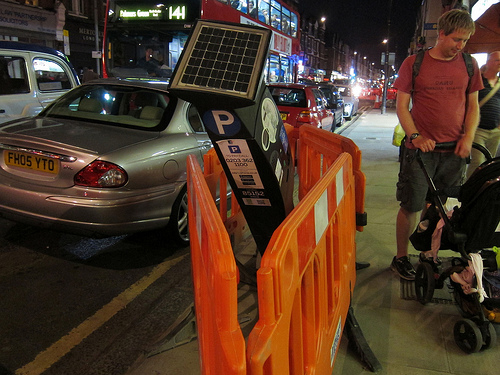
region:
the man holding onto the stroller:
[388, 11, 483, 283]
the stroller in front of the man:
[412, 132, 498, 352]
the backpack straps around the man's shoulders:
[409, 50, 474, 93]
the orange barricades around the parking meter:
[186, 122, 381, 374]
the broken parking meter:
[166, 19, 298, 259]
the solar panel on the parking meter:
[175, 23, 262, 96]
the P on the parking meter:
[209, 109, 234, 134]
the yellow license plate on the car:
[3, 152, 60, 173]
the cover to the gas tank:
[161, 159, 179, 181]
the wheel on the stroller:
[413, 261, 434, 304]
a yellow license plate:
[5, 144, 60, 177]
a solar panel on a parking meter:
[182, 24, 264, 96]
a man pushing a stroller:
[388, 4, 498, 353]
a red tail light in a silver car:
[75, 156, 132, 195]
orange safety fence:
[178, 123, 374, 370]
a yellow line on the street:
[7, 246, 202, 373]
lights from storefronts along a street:
[109, 4, 395, 98]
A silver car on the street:
[0, 73, 259, 253]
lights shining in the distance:
[340, 80, 375, 103]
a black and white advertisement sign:
[116, 5, 193, 22]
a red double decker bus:
[100, 0, 300, 83]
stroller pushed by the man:
[410, 140, 495, 355]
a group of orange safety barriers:
[185, 121, 365, 371]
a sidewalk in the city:
[122, 105, 497, 370]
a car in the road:
[0, 76, 231, 246]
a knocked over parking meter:
[166, 18, 294, 255]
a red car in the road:
[266, 82, 336, 132]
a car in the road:
[0, 40, 90, 123]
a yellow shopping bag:
[391, 121, 405, 146]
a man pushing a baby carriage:
[393, 8, 498, 353]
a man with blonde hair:
[433, 7, 473, 67]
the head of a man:
[435, 8, 475, 62]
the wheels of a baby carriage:
[453, 310, 495, 353]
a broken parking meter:
[176, 15, 306, 238]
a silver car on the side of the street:
[3, 59, 218, 251]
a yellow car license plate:
[1, 145, 60, 177]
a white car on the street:
[0, 28, 78, 123]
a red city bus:
[99, 0, 307, 103]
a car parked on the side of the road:
[262, 78, 335, 142]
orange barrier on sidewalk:
[194, 193, 256, 338]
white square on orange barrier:
[304, 191, 338, 238]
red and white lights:
[62, 154, 135, 200]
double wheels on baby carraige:
[457, 307, 495, 349]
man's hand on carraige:
[403, 128, 480, 169]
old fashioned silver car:
[35, 70, 179, 242]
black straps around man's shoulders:
[393, 45, 489, 90]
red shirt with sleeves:
[393, 52, 492, 157]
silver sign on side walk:
[366, 35, 401, 123]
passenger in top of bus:
[243, 0, 304, 29]